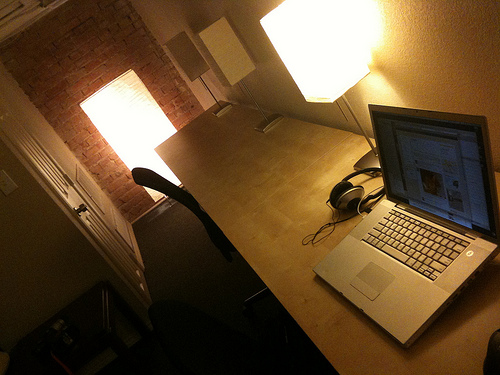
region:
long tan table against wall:
[150, 63, 485, 360]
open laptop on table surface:
[320, 97, 490, 367]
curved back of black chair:
[130, 145, 232, 251]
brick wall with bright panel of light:
[1, 11, 201, 221]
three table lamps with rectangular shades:
[160, 0, 385, 180]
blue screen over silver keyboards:
[315, 101, 492, 341]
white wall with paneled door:
[5, 75, 145, 292]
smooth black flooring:
[126, 190, 331, 370]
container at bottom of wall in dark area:
[0, 162, 145, 367]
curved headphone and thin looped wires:
[297, 150, 384, 250]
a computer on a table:
[237, 128, 491, 333]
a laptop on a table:
[285, 133, 494, 362]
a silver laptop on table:
[257, 53, 499, 356]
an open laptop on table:
[319, 83, 473, 374]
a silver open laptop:
[328, 86, 496, 334]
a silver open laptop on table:
[335, 91, 499, 356]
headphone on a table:
[282, 140, 414, 247]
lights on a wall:
[222, 2, 487, 155]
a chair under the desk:
[119, 148, 320, 334]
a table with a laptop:
[235, 126, 497, 331]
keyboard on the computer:
[363, 210, 478, 269]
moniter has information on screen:
[385, 129, 482, 229]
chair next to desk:
[131, 164, 236, 264]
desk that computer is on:
[244, 113, 359, 358]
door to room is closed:
[19, 115, 161, 262]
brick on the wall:
[62, 102, 155, 207]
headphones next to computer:
[331, 169, 374, 216]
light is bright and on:
[270, 6, 382, 98]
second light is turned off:
[171, 25, 225, 126]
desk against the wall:
[11, 284, 141, 355]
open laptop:
[300, 102, 498, 354]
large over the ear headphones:
[316, 160, 388, 222]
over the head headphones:
[321, 162, 392, 219]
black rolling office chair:
[112, 162, 311, 321]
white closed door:
[0, 104, 153, 302]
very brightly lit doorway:
[67, 58, 196, 211]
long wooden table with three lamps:
[147, 90, 484, 374]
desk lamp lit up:
[252, 1, 402, 179]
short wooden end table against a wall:
[0, 270, 160, 370]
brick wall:
[0, 0, 204, 222]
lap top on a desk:
[361, 103, 493, 343]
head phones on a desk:
[330, 162, 366, 212]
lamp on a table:
[255, 0, 375, 125]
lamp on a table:
[195, 15, 287, 136]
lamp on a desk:
[153, 35, 228, 125]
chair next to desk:
[115, 160, 202, 225]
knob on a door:
[66, 182, 107, 220]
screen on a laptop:
[368, 106, 483, 209]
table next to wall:
[69, 282, 135, 355]